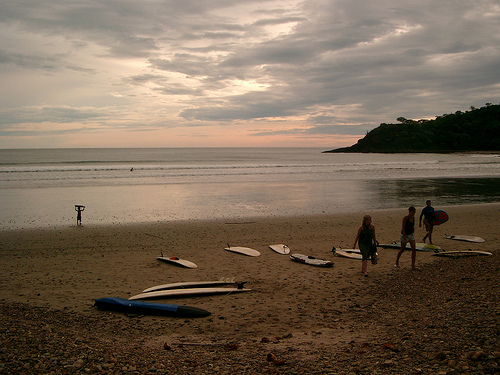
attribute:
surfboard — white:
[140, 236, 206, 274]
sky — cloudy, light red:
[1, 1, 490, 147]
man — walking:
[350, 215, 381, 277]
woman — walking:
[395, 205, 419, 270]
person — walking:
[414, 192, 439, 241]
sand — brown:
[0, 204, 500, 373]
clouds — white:
[172, 48, 297, 109]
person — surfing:
[128, 163, 132, 175]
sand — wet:
[2, 187, 483, 359]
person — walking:
[354, 210, 386, 278]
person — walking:
[388, 196, 425, 263]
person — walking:
[416, 190, 441, 250]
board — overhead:
[69, 199, 89, 210]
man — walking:
[419, 197, 445, 250]